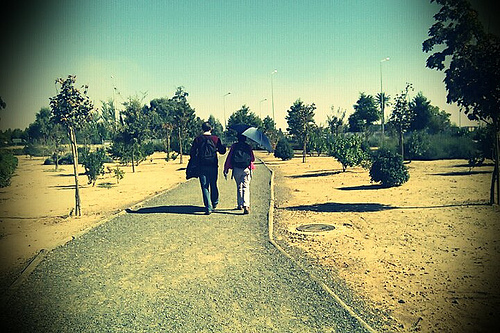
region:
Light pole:
[375, 48, 392, 144]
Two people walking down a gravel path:
[176, 115, 276, 227]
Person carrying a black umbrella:
[225, 118, 274, 213]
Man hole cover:
[285, 215, 345, 250]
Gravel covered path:
[128, 213, 248, 325]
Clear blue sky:
[154, 15, 349, 63]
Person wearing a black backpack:
[191, 120, 223, 195]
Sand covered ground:
[379, 201, 474, 301]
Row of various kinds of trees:
[285, 91, 455, 189]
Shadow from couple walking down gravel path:
[119, 186, 199, 224]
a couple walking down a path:
[166, 90, 271, 229]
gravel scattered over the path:
[140, 280, 203, 331]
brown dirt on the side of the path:
[383, 229, 445, 289]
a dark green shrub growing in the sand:
[356, 143, 423, 194]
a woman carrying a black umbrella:
[231, 120, 267, 206]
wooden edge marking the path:
[267, 183, 271, 237]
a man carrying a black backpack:
[181, 116, 223, 214]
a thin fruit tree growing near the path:
[40, 66, 99, 222]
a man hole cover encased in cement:
[285, 211, 363, 246]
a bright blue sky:
[129, 18, 393, 65]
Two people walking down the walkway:
[171, 80, 281, 282]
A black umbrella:
[241, 117, 278, 154]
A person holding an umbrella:
[215, 113, 275, 218]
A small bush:
[361, 146, 416, 200]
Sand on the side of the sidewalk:
[355, 196, 479, 298]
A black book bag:
[194, 132, 224, 170]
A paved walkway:
[108, 236, 248, 317]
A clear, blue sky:
[113, 15, 345, 65]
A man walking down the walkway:
[174, 116, 231, 249]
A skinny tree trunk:
[64, 125, 87, 224]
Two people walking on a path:
[176, 116, 277, 236]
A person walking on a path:
[180, 110, 221, 220]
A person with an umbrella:
[225, 115, 265, 212]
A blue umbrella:
[225, 115, 275, 167]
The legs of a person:
[190, 170, 225, 216]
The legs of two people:
[190, 171, 260, 216]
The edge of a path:
[262, 172, 307, 279]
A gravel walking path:
[99, 232, 304, 327]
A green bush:
[353, 146, 424, 201]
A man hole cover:
[273, 202, 358, 267]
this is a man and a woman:
[193, 122, 273, 211]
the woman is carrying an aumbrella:
[251, 128, 268, 139]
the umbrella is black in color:
[243, 125, 263, 134]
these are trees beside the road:
[58, 106, 175, 166]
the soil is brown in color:
[317, 227, 437, 265]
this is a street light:
[376, 55, 391, 75]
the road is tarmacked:
[116, 233, 251, 328]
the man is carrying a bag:
[202, 143, 215, 162]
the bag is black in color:
[236, 151, 251, 163]